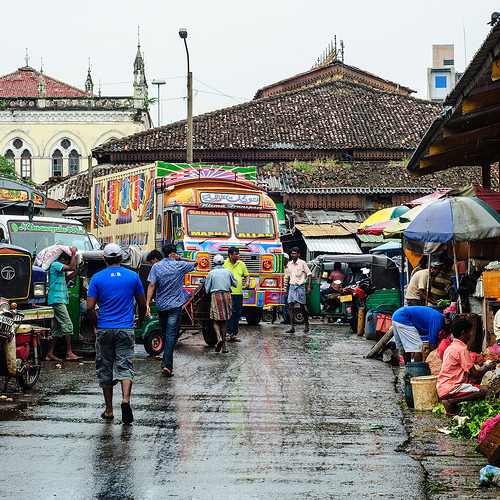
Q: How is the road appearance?
A: Wet.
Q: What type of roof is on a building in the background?
A: Shingles.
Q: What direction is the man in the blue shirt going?
A: Toward the big bus.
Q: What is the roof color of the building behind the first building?
A: Red.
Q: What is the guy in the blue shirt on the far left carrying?
A: A big bag over head.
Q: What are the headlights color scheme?
A: Orange.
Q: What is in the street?
A: The big bus and people walking.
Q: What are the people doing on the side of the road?
A: Working.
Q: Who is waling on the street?
A: The people.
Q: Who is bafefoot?
A: The man.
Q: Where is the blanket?
A: Man's head.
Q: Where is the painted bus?
A: Street.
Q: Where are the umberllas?
A: Side of street.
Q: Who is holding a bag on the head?
A: A man.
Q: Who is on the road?
A: Several people.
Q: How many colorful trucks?
A: 1.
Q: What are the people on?
A: Street.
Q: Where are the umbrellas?
A: To the right.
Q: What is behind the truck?
A: Building.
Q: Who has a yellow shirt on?
A: A man.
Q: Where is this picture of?
A: Market.